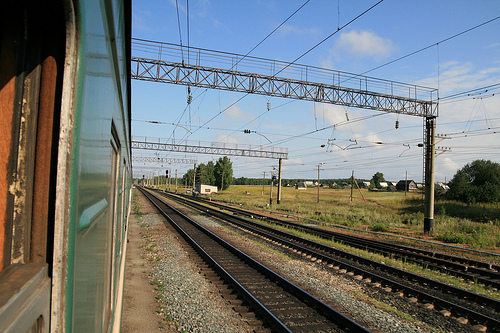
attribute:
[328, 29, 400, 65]
cloud — small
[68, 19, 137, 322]
rail — green, Light rail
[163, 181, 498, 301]
grass — green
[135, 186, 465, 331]
tracks — black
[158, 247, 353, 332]
gray ballast — grey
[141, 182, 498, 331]
train track — above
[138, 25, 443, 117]
scaffolding — metal 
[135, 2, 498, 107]
power lines — power 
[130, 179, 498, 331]
track — above , train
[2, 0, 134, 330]
train car — side , train , green 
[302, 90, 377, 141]
clouds — white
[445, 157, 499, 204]
green tree — green , distance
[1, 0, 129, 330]
green train — green 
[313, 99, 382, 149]
clouds — white 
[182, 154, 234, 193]
trees — green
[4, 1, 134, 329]
train — over 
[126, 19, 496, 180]
clouds — white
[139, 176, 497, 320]
tracks — train, black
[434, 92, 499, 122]
cloud — white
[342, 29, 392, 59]
clouds — white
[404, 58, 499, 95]
clouds — white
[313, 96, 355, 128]
clouds — white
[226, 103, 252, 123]
clouds — white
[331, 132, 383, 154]
clouds — white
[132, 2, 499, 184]
sky — blue, white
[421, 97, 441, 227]
poles — grey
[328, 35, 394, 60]
cloud — white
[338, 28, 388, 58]
clouds — white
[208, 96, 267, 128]
clouds — white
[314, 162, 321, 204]
pole — telephone , brown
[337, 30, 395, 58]
clouds — white puffy 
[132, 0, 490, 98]
blue sky — blue 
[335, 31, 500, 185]
clouds — white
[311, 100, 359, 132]
clouds — white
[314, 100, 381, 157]
clouds — white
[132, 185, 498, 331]
train tracks — train  , long set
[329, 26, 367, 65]
cloud — white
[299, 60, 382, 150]
clouds — white 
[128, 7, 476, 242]
sky — blue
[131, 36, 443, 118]
bars — metal 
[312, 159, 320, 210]
pole — tall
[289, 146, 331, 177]
sky — blue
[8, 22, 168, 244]
train car — green , brown train 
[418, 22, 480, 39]
sky — blue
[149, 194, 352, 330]
train tracks — steel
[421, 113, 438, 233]
pole — metal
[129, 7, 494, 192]
clouds — white 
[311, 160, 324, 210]
pole — telephone , wood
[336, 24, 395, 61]
cloud — white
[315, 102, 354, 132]
cloud — white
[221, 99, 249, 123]
cloud — white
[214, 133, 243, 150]
cloud — white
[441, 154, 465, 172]
cloud — white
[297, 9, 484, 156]
clouds — white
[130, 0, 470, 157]
sky — blue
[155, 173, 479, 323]
tracks — train , side 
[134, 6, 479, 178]
sky — blue 